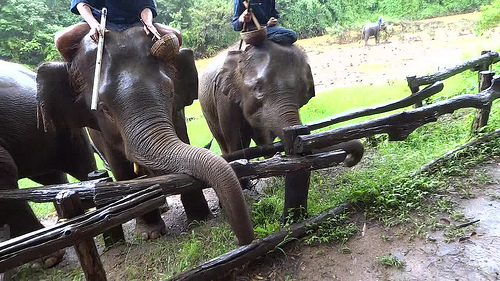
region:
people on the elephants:
[3, 10, 348, 254]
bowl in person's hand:
[141, 30, 186, 51]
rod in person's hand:
[87, 7, 109, 119]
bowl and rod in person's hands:
[234, 8, 269, 47]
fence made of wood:
[35, 68, 457, 235]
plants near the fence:
[370, 150, 422, 176]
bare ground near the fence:
[366, 236, 476, 270]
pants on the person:
[249, 19, 296, 49]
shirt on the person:
[73, 2, 163, 19]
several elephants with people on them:
[0, 0, 390, 244]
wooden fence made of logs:
[3, 49, 497, 279]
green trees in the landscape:
[1, 0, 497, 64]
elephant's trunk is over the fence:
[35, 22, 253, 247]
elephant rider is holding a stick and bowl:
[55, 0, 182, 110]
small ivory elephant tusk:
[130, 160, 140, 175]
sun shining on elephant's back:
[1, 55, 38, 92]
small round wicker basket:
[148, 30, 178, 58]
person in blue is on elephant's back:
[362, 17, 389, 44]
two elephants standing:
[14, 19, 329, 250]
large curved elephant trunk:
[97, 112, 258, 269]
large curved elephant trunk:
[258, 112, 322, 247]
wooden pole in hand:
[60, 12, 124, 132]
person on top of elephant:
[71, 0, 181, 44]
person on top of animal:
[222, 0, 299, 45]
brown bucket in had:
[238, 25, 266, 42]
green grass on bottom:
[348, 166, 419, 213]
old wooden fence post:
[352, 72, 492, 153]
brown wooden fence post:
[7, 196, 148, 257]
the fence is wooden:
[7, 76, 497, 277]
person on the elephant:
[70, 6, 162, 32]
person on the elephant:
[232, 3, 304, 40]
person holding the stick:
[86, 11, 116, 113]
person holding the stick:
[233, 0, 253, 48]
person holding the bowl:
[138, 12, 183, 62]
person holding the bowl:
[233, 23, 279, 43]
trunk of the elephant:
[126, 121, 255, 261]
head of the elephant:
[215, 46, 392, 176]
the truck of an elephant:
[274, 108, 361, 168]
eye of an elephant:
[253, 81, 266, 96]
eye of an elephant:
[98, 99, 108, 111]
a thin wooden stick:
[89, 8, 108, 110]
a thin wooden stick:
[243, 1, 262, 27]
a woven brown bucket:
[149, 35, 176, 62]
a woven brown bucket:
[239, 23, 266, 46]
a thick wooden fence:
[288, 52, 499, 214]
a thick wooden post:
[282, 127, 312, 218]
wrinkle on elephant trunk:
[130, 113, 164, 128]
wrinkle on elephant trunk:
[127, 115, 166, 142]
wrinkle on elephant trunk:
[142, 128, 169, 154]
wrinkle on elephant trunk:
[157, 138, 177, 159]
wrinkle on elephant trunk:
[166, 141, 183, 159]